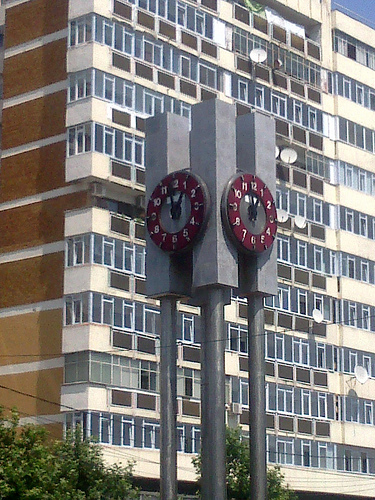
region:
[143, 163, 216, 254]
a clock tower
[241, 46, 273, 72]
a satellite dish on a building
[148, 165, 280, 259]
2 clocks on a tower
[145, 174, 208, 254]
a clock that reads 12:59pm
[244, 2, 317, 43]
cloth hanging on a porch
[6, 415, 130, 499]
tree underneath power lines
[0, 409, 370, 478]
power lines hanging above the trees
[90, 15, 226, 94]
a row of windows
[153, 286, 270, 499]
four metal poles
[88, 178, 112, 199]
an air conditioning unit on the side of the building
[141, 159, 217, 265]
the clock is red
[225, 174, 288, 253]
the clock is red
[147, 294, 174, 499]
the pole is gray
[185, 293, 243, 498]
the pole is gray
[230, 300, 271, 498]
the pole is gray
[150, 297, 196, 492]
the pole is gray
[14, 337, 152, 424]
black electrical lines in the air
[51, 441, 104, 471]
green leaves on trees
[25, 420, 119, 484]
tall green trees near the building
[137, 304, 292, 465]
tall gray iron columns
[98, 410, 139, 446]
windows in front of building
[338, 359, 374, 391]
large white cable dish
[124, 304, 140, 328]
white curtain in window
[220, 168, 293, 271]
large round purple clock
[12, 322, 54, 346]
brown paint on wall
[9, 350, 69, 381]
white stripe on wall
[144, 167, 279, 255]
Two red and gray clock faces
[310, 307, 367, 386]
Two small satellite dishes on a building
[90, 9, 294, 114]
A row of windows in a building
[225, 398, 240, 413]
One air conditioning unit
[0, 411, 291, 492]
Green trees around the base of a building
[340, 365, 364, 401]
Shadow of a satellite dish on a building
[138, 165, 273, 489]
Four pillars holding up a clock tower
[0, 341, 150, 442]
Power lines hanging off a building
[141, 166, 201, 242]
A clock reading one o'clock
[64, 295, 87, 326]
One open window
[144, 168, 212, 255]
A large red clock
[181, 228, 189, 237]
Number 5 on clock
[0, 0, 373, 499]
A tall building in the distance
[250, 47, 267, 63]
A white satellite dish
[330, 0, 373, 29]
blue sky above buildiing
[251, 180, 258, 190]
number 12 on clock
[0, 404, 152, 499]
A tree in the foreground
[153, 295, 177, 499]
a thick black pole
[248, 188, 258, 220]
A black clock hand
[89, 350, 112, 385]
A window on a building